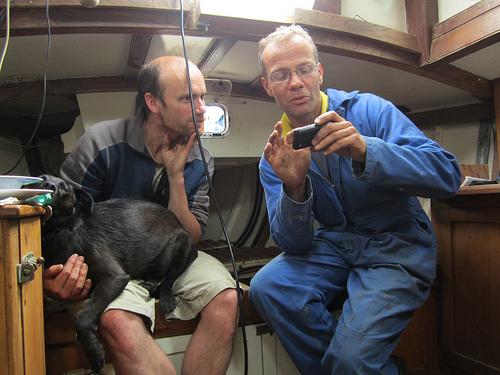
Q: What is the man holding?
A: A sleeping black dog.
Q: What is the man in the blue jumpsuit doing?
A: Using a black device.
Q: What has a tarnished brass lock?
A: Medium brown wood cabinet.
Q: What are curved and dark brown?
A: Wooden rafter.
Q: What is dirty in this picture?
A: Trouser portion of the blue coveralls.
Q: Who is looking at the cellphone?
A: Two men.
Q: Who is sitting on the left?
A: Man holding black dog on lap.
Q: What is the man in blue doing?
A: Holding phone in both hands.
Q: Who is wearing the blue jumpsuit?
A: The man on right.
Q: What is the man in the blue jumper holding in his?
A: Cell Phone.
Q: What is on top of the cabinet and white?
A: Plate.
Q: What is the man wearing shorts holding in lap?
A: Cat.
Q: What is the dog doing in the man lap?
A: Sleeping.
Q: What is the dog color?
A: Black.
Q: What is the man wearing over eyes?
A: Glasses.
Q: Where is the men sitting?
A: Bench.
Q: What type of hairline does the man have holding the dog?
A: Bald.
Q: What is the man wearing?
A: Blue jumper.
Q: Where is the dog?
A: Sitting on man's lap.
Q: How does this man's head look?
A: Going bald.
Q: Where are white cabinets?
A: Under a bench.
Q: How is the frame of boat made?
A: Out of wood.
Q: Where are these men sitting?
A: In a boat cabin.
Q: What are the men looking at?
A: Cell phone.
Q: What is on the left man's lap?
A: A dog.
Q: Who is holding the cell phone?
A: The man on the right.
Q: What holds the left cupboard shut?
A: The lock.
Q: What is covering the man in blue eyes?
A: Glasses.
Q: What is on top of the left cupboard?
A: Dishes.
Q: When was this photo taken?
A: During the day.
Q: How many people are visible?
A: Two.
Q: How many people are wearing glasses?
A: One.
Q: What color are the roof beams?
A: Brown.